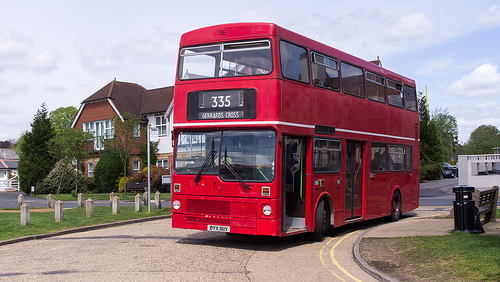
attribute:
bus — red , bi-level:
[166, 21, 423, 238]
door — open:
[283, 134, 313, 236]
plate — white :
[207, 221, 232, 233]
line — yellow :
[318, 227, 364, 280]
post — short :
[52, 201, 62, 221]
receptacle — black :
[449, 181, 483, 230]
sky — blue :
[4, 1, 499, 161]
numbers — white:
[204, 86, 240, 115]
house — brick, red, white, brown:
[66, 75, 169, 195]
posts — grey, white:
[8, 181, 168, 233]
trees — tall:
[17, 104, 80, 198]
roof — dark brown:
[79, 75, 171, 133]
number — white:
[204, 84, 236, 113]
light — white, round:
[264, 203, 273, 223]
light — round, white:
[257, 204, 271, 216]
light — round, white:
[168, 203, 178, 210]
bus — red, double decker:
[181, 26, 431, 253]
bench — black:
[475, 184, 498, 224]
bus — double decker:
[172, 17, 415, 255]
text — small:
[195, 101, 242, 121]